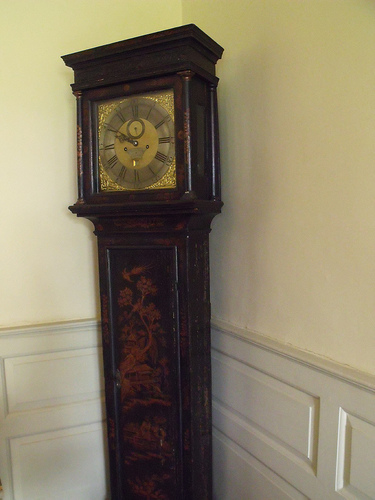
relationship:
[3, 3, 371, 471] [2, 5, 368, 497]
walls of room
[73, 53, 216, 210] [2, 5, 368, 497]
clock in room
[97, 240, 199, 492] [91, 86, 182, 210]
door on front of clock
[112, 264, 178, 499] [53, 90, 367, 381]
design on wallwood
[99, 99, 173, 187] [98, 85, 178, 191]
numerals on clock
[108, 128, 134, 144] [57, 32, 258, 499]
hands on clock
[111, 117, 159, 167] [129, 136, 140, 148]
gold circle in middle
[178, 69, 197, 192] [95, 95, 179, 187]
column on clock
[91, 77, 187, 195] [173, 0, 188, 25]
clock in corner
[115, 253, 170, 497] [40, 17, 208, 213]
image on clock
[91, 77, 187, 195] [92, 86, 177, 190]
clock has gold face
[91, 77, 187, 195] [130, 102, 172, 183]
clock has numerals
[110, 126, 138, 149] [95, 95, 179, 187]
hands on clock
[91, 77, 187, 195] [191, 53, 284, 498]
clock casts shadow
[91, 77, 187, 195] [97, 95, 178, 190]
clock has face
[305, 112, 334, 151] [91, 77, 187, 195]
ground on clock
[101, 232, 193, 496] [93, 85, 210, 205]
decor on clock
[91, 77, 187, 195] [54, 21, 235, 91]
clock has top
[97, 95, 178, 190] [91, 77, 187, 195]
face on clock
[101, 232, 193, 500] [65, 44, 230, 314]
decor on clock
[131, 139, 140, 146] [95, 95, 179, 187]
center on clock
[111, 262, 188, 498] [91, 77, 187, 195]
carving on clock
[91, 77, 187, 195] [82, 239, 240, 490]
clock in corner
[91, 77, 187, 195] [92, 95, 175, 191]
clock has roman numerals